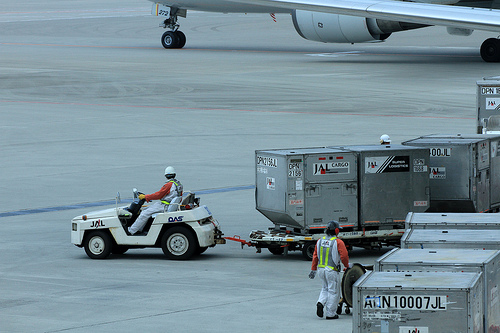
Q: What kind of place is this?
A: It is an airport.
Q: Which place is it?
A: It is an airport.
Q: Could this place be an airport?
A: Yes, it is an airport.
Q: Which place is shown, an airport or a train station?
A: It is an airport.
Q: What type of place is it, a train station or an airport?
A: It is an airport.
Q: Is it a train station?
A: No, it is an airport.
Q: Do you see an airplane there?
A: Yes, there is an airplane.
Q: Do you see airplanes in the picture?
A: Yes, there is an airplane.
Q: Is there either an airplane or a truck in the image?
A: Yes, there is an airplane.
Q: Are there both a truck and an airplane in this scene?
A: Yes, there are both an airplane and a truck.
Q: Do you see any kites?
A: No, there are no kites.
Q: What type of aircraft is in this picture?
A: The aircraft is an airplane.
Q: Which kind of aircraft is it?
A: The aircraft is an airplane.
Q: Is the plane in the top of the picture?
A: Yes, the plane is in the top of the image.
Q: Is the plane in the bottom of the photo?
A: No, the plane is in the top of the image.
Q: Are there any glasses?
A: No, there are no glasses.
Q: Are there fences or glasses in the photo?
A: No, there are no glasses or fences.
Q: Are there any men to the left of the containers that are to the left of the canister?
A: Yes, there is a man to the left of the containers.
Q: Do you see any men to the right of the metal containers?
A: No, the man is to the left of the containers.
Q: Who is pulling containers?
A: The man is pulling containers.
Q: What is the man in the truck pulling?
A: The man is pulling containers.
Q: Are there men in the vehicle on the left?
A: Yes, there is a man in the truck.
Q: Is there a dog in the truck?
A: No, there is a man in the truck.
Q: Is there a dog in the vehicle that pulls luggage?
A: No, there is a man in the truck.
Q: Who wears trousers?
A: The man wears trousers.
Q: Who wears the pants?
A: The man wears trousers.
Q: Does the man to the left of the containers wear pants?
A: Yes, the man wears pants.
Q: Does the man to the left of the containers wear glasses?
A: No, the man wears pants.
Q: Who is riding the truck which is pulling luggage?
A: The man is riding the truck.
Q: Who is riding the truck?
A: The man is riding the truck.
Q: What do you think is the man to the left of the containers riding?
A: The man is riding the truck.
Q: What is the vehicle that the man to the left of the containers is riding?
A: The vehicle is a truck.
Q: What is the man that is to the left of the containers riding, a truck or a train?
A: The man is riding a truck.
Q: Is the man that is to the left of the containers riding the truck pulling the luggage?
A: Yes, the man is riding the truck.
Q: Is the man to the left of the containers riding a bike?
A: No, the man is riding the truck.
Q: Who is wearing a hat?
A: The man is wearing a hat.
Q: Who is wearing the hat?
A: The man is wearing a hat.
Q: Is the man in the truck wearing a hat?
A: Yes, the man is wearing a hat.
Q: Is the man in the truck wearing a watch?
A: No, the man is wearing a hat.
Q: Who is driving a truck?
A: The man is driving a truck.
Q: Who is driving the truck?
A: The man is driving a truck.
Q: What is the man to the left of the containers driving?
A: The man is driving a truck.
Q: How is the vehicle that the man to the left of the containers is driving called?
A: The vehicle is a truck.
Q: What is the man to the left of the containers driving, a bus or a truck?
A: The man is driving a truck.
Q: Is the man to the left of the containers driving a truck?
A: Yes, the man is driving a truck.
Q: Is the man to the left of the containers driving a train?
A: No, the man is driving a truck.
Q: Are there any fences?
A: No, there are no fences.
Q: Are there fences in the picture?
A: No, there are no fences.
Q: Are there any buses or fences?
A: No, there are no fences or buses.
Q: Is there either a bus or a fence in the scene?
A: No, there are no fences or buses.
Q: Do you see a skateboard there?
A: No, there are no skateboards.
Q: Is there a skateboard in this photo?
A: No, there are no skateboards.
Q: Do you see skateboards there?
A: No, there are no skateboards.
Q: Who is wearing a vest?
A: The man is wearing a vest.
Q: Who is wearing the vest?
A: The man is wearing a vest.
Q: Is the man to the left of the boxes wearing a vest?
A: Yes, the man is wearing a vest.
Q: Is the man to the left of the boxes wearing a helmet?
A: No, the man is wearing a vest.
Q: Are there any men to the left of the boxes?
A: Yes, there is a man to the left of the boxes.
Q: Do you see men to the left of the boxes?
A: Yes, there is a man to the left of the boxes.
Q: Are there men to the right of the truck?
A: Yes, there is a man to the right of the truck.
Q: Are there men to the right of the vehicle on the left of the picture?
A: Yes, there is a man to the right of the truck.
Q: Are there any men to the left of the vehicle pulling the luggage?
A: No, the man is to the right of the truck.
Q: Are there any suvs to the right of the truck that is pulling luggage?
A: No, there is a man to the right of the truck.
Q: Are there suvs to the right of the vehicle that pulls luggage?
A: No, there is a man to the right of the truck.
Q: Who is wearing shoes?
A: The man is wearing shoes.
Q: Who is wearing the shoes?
A: The man is wearing shoes.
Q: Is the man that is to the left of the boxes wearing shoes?
A: Yes, the man is wearing shoes.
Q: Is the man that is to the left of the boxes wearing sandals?
A: No, the man is wearing shoes.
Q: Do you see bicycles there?
A: No, there are no bicycles.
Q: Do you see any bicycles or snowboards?
A: No, there are no bicycles or snowboards.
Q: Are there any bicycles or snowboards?
A: No, there are no bicycles or snowboards.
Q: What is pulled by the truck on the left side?
A: The luggage is pulled by the truck.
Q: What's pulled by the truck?
A: The luggage is pulled by the truck.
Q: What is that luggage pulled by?
A: The luggage is pulled by the truck.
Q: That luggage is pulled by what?
A: The luggage is pulled by the truck.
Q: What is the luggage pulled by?
A: The luggage is pulled by the truck.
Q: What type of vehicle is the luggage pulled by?
A: The luggage is pulled by the truck.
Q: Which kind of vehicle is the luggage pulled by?
A: The luggage is pulled by the truck.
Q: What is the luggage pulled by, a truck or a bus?
A: The luggage is pulled by a truck.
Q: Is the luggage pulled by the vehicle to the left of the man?
A: Yes, the luggage is pulled by the truck.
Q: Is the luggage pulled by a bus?
A: No, the luggage is pulled by the truck.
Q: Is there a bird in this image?
A: No, there are no birds.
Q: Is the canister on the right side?
A: Yes, the canister is on the right of the image.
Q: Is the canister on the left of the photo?
A: No, the canister is on the right of the image.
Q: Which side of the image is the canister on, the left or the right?
A: The canister is on the right of the image.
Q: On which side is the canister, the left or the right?
A: The canister is on the right of the image.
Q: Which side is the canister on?
A: The canister is on the right of the image.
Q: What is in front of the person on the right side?
A: The canister is in front of the person.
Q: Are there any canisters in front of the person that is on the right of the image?
A: Yes, there is a canister in front of the person.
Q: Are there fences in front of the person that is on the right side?
A: No, there is a canister in front of the person.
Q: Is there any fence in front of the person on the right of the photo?
A: No, there is a canister in front of the person.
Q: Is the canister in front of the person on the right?
A: Yes, the canister is in front of the person.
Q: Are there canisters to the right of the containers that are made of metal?
A: Yes, there is a canister to the right of the containers.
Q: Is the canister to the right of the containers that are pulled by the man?
A: Yes, the canister is to the right of the containers.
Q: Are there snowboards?
A: No, there are no snowboards.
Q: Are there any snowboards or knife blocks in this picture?
A: No, there are no snowboards or knife blocks.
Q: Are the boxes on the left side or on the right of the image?
A: The boxes are on the right of the image.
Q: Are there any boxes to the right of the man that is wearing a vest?
A: Yes, there are boxes to the right of the man.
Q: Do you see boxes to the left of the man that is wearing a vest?
A: No, the boxes are to the right of the man.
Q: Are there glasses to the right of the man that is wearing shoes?
A: No, there are boxes to the right of the man.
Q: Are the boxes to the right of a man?
A: Yes, the boxes are to the right of a man.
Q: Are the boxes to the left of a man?
A: No, the boxes are to the right of a man.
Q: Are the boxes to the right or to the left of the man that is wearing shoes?
A: The boxes are to the right of the man.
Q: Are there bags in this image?
A: No, there are no bags.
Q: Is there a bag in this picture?
A: No, there are no bags.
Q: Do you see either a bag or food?
A: No, there are no bags or food.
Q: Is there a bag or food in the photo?
A: No, there are no bags or food.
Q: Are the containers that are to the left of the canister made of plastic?
A: No, the containers are made of metal.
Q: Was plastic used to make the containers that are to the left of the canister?
A: No, the containers are made of metal.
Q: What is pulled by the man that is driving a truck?
A: The containers are pulled by the man.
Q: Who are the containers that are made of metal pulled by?
A: The containers are pulled by the man.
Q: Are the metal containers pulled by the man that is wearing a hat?
A: Yes, the containers are pulled by the man.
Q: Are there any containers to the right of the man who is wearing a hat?
A: Yes, there are containers to the right of the man.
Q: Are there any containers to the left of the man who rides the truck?
A: No, the containers are to the right of the man.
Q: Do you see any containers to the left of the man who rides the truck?
A: No, the containers are to the right of the man.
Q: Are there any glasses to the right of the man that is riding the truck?
A: No, there are containers to the right of the man.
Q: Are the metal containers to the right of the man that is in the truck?
A: Yes, the containers are to the right of the man.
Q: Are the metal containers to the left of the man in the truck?
A: No, the containers are to the right of the man.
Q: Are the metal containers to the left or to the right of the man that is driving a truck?
A: The containers are to the right of the man.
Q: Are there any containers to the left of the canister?
A: Yes, there are containers to the left of the canister.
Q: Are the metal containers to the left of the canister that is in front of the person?
A: Yes, the containers are to the left of the canister.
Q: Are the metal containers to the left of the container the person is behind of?
A: Yes, the containers are to the left of the canister.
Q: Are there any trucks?
A: Yes, there is a truck.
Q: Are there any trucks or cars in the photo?
A: Yes, there is a truck.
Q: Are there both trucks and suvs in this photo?
A: No, there is a truck but no suvs.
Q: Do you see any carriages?
A: No, there are no carriages.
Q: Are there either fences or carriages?
A: No, there are no carriages or fences.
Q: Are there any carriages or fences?
A: No, there are no carriages or fences.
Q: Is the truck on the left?
A: Yes, the truck is on the left of the image.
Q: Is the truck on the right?
A: No, the truck is on the left of the image.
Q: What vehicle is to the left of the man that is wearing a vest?
A: The vehicle is a truck.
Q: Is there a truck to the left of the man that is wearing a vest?
A: Yes, there is a truck to the left of the man.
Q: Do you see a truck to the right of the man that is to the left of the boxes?
A: No, the truck is to the left of the man.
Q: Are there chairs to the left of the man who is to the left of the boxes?
A: No, there is a truck to the left of the man.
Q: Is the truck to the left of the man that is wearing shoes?
A: Yes, the truck is to the left of the man.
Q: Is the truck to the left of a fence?
A: No, the truck is to the left of the man.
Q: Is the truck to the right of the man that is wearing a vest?
A: No, the truck is to the left of the man.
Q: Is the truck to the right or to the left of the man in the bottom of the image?
A: The truck is to the left of the man.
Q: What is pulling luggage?
A: The truck is pulling luggage.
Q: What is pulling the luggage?
A: The truck is pulling luggage.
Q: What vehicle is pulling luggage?
A: The vehicle is a truck.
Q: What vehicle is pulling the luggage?
A: The vehicle is a truck.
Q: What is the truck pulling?
A: The truck is pulling luggage.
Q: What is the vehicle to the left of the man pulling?
A: The truck is pulling luggage.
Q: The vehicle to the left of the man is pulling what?
A: The truck is pulling luggage.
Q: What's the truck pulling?
A: The truck is pulling luggage.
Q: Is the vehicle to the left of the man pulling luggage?
A: Yes, the truck is pulling luggage.